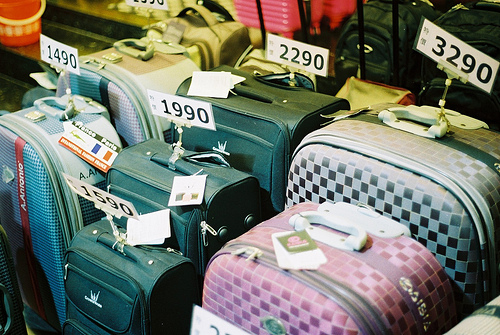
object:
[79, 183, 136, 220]
number 1590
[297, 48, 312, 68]
9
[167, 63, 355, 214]
black luggage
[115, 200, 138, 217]
number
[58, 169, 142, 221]
card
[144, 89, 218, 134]
sign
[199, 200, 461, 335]
luggage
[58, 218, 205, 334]
black bag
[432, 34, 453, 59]
number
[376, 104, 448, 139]
handle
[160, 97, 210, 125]
1990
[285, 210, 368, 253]
handle